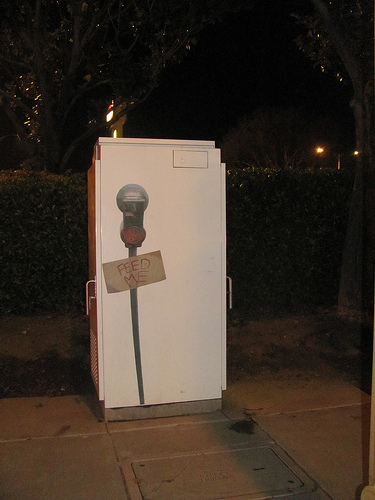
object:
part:
[67, 438, 222, 489]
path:
[7, 377, 375, 499]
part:
[104, 27, 127, 66]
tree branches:
[0, 2, 211, 137]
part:
[147, 268, 159, 276]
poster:
[98, 249, 179, 293]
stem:
[335, 111, 374, 319]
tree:
[283, 6, 374, 316]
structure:
[77, 127, 239, 424]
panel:
[118, 437, 317, 498]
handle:
[121, 224, 150, 247]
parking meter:
[116, 182, 156, 410]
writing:
[118, 258, 155, 287]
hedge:
[1, 172, 346, 317]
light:
[316, 140, 328, 156]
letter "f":
[116, 262, 128, 277]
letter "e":
[129, 261, 140, 270]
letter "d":
[140, 258, 153, 270]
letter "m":
[120, 272, 139, 291]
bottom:
[96, 395, 228, 424]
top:
[86, 131, 222, 166]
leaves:
[289, 192, 301, 231]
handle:
[83, 276, 96, 316]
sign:
[107, 95, 127, 127]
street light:
[311, 145, 365, 160]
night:
[225, 35, 296, 103]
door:
[85, 164, 106, 401]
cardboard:
[101, 182, 167, 407]